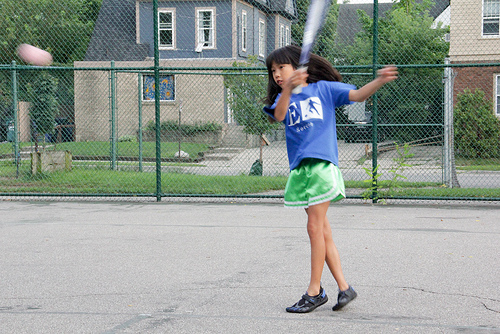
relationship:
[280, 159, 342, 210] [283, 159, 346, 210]
shorts with shorts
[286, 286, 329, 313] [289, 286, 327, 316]
shoe on foot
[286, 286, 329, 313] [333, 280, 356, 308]
shoe on foot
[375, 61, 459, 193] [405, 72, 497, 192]
section of fence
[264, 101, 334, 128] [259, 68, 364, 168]
emblem on shirt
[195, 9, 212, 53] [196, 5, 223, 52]
curtain on window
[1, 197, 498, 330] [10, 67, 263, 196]
concrete under fence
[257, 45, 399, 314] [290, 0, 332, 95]
girl holding bat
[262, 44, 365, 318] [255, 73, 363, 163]
girl wearing shirt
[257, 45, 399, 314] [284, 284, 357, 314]
girl wearing black shoes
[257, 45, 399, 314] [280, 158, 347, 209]
girl wearing shorts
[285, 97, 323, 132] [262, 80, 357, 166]
logo on shirt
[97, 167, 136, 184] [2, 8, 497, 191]
grass by fence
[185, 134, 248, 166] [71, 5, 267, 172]
steps are by house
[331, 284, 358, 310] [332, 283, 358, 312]
black shoes on foot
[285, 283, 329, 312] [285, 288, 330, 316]
shoe on foot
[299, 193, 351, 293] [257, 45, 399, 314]
legs are on girl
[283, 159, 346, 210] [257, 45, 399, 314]
shorts are on girl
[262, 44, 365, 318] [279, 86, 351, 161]
girl wearing shirt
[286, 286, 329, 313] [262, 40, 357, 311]
shoe on a girl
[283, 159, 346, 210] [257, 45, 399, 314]
shorts on a girl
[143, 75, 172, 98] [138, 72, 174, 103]
curtain in a window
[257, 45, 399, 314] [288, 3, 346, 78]
girl swinging bat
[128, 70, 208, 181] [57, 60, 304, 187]
poles on fence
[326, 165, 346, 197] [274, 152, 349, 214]
stripe on shorts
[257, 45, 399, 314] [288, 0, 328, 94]
girl swinging bat